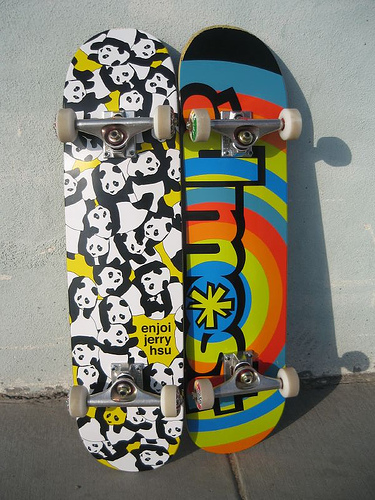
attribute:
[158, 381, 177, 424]
wheel — white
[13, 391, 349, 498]
ground — concrete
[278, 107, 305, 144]
wheel — white